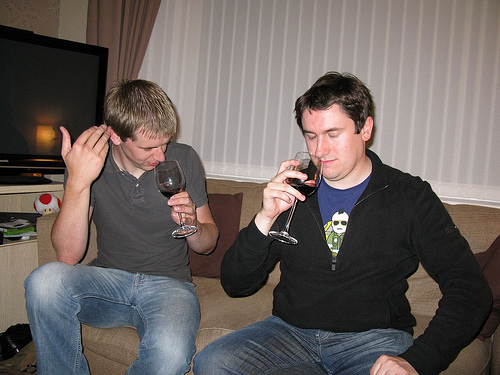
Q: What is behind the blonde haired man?
A: A pillow.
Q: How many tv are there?
A: 1.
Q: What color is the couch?
A: Tan.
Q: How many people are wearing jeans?
A: 2.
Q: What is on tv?
A: Nothing.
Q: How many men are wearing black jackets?
A: 1.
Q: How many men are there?
A: 2.